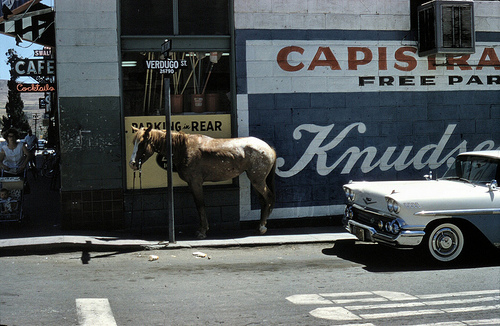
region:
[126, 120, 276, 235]
a brown and white horse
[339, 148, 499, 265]
an antique white car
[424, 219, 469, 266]
a white wall front tire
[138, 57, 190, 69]
a street name sign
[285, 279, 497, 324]
street printed stop sign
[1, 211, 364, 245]
a paved city sidewalk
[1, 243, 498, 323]
a paved city street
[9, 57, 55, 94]
a business promotional sign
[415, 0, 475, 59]
a wall mounted air conditioning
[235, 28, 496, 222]
a wall painted advertisement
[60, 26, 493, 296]
Horse on the sidewalk alone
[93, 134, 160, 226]
Reins of horse on sidewalk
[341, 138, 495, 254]
Classic car parked at the curb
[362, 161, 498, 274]
Classic car is blue and white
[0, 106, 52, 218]
Woman pushing child in stroller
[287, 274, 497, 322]
White letters painted on street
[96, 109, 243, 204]
Horse standing in front of parking sign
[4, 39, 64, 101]
Neon cafe sign on front of bnuilding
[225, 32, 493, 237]
Sign painted on side of building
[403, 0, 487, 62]
Air conditioner on side of building is old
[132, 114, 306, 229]
horse standing on side walk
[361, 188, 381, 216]
logo on front of car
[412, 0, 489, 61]
grey metal air conditioner on side of building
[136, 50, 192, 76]
black and white metal street sign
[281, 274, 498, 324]
white painting on pavement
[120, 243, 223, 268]
trash laying on road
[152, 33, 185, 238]
grey metal street sign pole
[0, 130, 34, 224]
woman pushing stroller on sidewalk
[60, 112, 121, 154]
chipped paint on side of building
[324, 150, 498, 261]
white car parked beside road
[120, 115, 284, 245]
horse on the street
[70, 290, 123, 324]
line painted in the road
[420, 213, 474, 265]
tire on a car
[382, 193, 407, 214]
headlight of a car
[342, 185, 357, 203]
headlight of a car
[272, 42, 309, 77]
painted red letter on a wall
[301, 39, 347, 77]
painted red letter on a wall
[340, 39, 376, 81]
painted red letter on a wall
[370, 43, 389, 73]
painted red letter on a wall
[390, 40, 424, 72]
painted red letter on a wall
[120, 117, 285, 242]
Horse in front of the building.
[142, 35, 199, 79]
Street signs on a pole.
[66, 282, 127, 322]
White line on the street.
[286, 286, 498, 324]
Stop on the ground.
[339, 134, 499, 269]
The car is parked.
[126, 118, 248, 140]
Parking in rear on the sign.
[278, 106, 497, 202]
White writing on the building.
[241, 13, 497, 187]
The building is brick.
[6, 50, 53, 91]
Cafe on the sign.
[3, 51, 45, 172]
Tree next to the building.